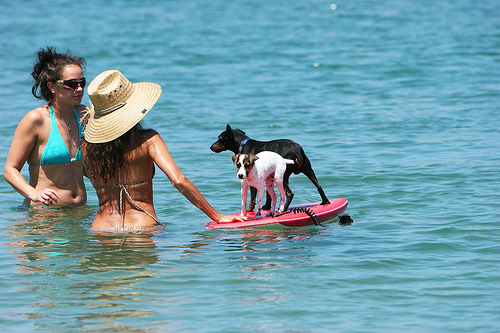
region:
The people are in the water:
[5, 31, 201, 308]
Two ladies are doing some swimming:
[0, 17, 191, 327]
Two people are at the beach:
[0, 30, 206, 328]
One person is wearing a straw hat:
[0, 38, 197, 328]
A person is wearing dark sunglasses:
[0, 25, 203, 310]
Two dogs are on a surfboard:
[205, 75, 358, 281]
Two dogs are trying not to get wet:
[208, 78, 363, 273]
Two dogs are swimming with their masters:
[3, 27, 405, 309]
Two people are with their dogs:
[0, 38, 487, 299]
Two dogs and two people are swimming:
[2, 35, 491, 303]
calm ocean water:
[363, 50, 489, 296]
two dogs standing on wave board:
[209, 122, 347, 226]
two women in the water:
[3, 45, 221, 241]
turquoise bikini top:
[33, 98, 93, 161]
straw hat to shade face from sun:
[82, 70, 158, 137]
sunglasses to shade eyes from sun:
[56, 75, 88, 87]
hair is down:
[80, 140, 141, 180]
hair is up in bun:
[26, 45, 92, 76]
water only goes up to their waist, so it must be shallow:
[13, 180, 168, 251]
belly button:
[69, 189, 81, 204]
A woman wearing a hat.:
[73, 67, 249, 232]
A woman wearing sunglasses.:
[1, 45, 86, 210]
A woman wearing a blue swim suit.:
[0, 41, 85, 206]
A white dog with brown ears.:
[225, 150, 295, 220]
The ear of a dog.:
[245, 150, 260, 165]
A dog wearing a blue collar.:
[205, 120, 325, 210]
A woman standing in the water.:
[75, 65, 245, 245]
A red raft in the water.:
[200, 195, 355, 230]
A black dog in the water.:
[210, 120, 330, 205]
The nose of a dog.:
[235, 172, 245, 178]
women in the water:
[3, 42, 219, 239]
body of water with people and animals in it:
[0, 15, 483, 315]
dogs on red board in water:
[198, 106, 355, 246]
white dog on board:
[233, 153, 296, 207]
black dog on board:
[206, 122, 328, 203]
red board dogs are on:
[195, 198, 353, 229]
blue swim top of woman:
[29, 104, 93, 162]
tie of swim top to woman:
[96, 178, 157, 202]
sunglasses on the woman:
[29, 70, 89, 89]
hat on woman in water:
[83, 69, 159, 149]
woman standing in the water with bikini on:
[71, 123, 250, 273]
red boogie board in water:
[202, 193, 357, 235]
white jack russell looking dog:
[230, 146, 297, 223]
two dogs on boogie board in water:
[201, 119, 352, 236]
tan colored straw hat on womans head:
[75, 66, 165, 145]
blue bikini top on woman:
[24, 103, 93, 171]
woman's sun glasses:
[50, 72, 88, 94]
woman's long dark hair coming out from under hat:
[72, 118, 152, 189]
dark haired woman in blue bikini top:
[1, 39, 92, 208]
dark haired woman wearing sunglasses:
[27, 37, 96, 126]